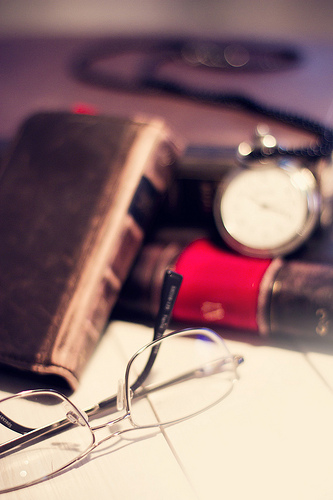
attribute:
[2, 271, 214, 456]
glasses — clear, black, shiny, small, thin, silver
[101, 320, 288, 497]
table — white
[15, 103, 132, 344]
book — black, brown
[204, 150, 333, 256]
watch — white, round, small